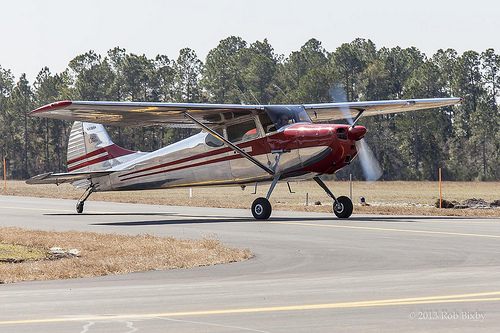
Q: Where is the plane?
A: On the road.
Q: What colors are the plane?
A: Silver and red.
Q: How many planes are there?
A: One.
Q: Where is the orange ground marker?
A: Behind the plane.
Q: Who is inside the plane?
A: The pilot.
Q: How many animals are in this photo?
A: None.